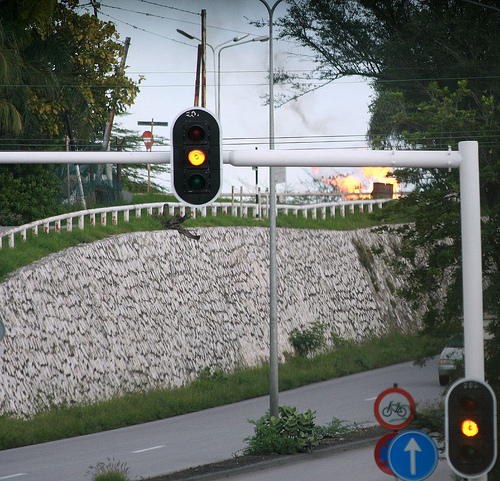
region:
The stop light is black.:
[166, 105, 226, 207]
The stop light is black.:
[438, 375, 498, 477]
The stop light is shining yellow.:
[432, 372, 498, 479]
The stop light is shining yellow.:
[168, 105, 225, 205]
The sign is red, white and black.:
[374, 386, 415, 428]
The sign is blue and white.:
[383, 430, 441, 479]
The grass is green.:
[41, 409, 103, 430]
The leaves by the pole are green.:
[253, 407, 317, 449]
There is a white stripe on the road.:
[123, 439, 172, 456]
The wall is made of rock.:
[99, 291, 187, 353]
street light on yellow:
[163, 99, 235, 214]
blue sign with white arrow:
[388, 429, 433, 476]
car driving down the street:
[430, 323, 475, 379]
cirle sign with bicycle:
[368, 371, 414, 426]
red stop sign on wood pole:
[132, 130, 154, 152]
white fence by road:
[5, 197, 413, 222]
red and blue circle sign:
[376, 430, 396, 470]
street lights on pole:
[173, 17, 273, 137]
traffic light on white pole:
[440, 148, 487, 473]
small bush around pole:
[252, 390, 322, 446]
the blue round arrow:
[388, 434, 443, 476]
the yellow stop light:
[438, 417, 484, 479]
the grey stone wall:
[77, 272, 272, 372]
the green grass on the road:
[20, 383, 209, 424]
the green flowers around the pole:
[253, 409, 337, 455]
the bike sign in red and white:
[368, 387, 422, 419]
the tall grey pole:
[255, 232, 296, 400]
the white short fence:
[9, 219, 86, 237]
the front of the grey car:
[435, 349, 467, 382]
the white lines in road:
[114, 429, 244, 456]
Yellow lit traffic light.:
[122, 72, 249, 236]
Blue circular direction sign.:
[377, 435, 452, 466]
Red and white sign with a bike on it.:
[355, 378, 417, 433]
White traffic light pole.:
[40, 138, 499, 279]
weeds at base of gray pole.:
[194, 377, 314, 479]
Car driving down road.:
[386, 336, 488, 391]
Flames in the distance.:
[304, 162, 409, 224]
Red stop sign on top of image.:
[121, 127, 162, 192]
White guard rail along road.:
[20, 211, 204, 249]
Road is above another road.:
[11, 105, 203, 464]